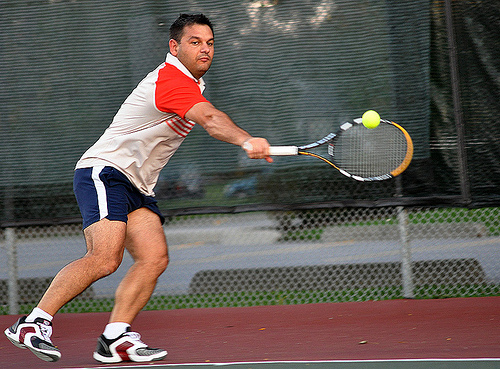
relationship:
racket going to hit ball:
[268, 117, 413, 184] [357, 105, 382, 131]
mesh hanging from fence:
[6, 1, 430, 187] [3, 0, 499, 315]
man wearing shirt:
[4, 10, 275, 362] [73, 54, 207, 194]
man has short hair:
[4, 10, 275, 362] [168, 13, 214, 43]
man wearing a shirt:
[4, 10, 275, 362] [73, 54, 207, 194]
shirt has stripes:
[73, 54, 207, 194] [164, 111, 194, 138]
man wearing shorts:
[4, 10, 275, 362] [71, 161, 162, 231]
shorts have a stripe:
[71, 161, 162, 231] [90, 167, 106, 220]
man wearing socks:
[4, 10, 275, 362] [24, 306, 132, 339]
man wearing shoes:
[4, 10, 275, 362] [3, 310, 170, 366]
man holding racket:
[4, 10, 275, 362] [268, 117, 413, 184]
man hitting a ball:
[4, 10, 275, 362] [357, 105, 382, 131]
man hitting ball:
[4, 10, 275, 362] [357, 105, 382, 131]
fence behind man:
[3, 0, 499, 315] [4, 10, 275, 362]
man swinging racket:
[4, 10, 275, 362] [268, 117, 413, 184]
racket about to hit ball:
[268, 117, 413, 184] [357, 105, 382, 131]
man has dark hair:
[4, 10, 275, 362] [168, 13, 214, 43]